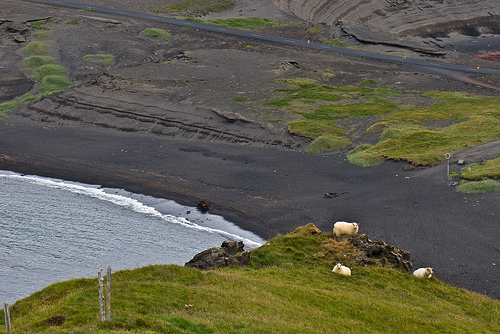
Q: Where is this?
A: This is at the beach.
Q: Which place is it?
A: It is a beach.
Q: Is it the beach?
A: Yes, it is the beach.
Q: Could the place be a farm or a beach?
A: It is a beach.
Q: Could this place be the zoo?
A: No, it is the beach.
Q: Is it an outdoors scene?
A: Yes, it is outdoors.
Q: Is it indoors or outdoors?
A: It is outdoors.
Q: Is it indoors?
A: No, it is outdoors.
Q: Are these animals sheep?
A: Yes, all the animals are sheep.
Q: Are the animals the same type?
A: Yes, all the animals are sheep.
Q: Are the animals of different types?
A: No, all the animals are sheep.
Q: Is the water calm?
A: Yes, the water is calm.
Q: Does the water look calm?
A: Yes, the water is calm.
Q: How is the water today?
A: The water is calm.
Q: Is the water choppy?
A: No, the water is calm.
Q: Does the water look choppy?
A: No, the water is calm.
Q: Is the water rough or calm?
A: The water is calm.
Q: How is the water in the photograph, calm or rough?
A: The water is calm.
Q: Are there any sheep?
A: Yes, there is a sheep.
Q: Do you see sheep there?
A: Yes, there is a sheep.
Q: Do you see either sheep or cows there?
A: Yes, there is a sheep.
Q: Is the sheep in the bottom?
A: Yes, the sheep is in the bottom of the image.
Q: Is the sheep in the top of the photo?
A: No, the sheep is in the bottom of the image.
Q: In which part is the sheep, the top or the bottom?
A: The sheep is in the bottom of the image.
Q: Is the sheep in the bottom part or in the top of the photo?
A: The sheep is in the bottom of the image.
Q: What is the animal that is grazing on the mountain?
A: The animal is a sheep.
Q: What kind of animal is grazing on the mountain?
A: The animal is a sheep.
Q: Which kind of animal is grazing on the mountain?
A: The animal is a sheep.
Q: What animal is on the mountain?
A: The animal is a sheep.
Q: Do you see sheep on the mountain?
A: Yes, there is a sheep on the mountain.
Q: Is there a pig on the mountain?
A: No, there is a sheep on the mountain.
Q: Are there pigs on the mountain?
A: No, there is a sheep on the mountain.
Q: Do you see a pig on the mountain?
A: No, there is a sheep on the mountain.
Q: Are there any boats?
A: No, there are no boats.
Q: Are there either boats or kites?
A: No, there are no boats or kites.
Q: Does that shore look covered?
A: Yes, the shore is covered.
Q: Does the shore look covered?
A: Yes, the shore is covered.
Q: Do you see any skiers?
A: No, there are no skiers.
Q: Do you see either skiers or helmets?
A: No, there are no skiers or helmets.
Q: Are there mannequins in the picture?
A: No, there are no mannequins.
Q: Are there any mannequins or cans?
A: No, there are no mannequins or cans.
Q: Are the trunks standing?
A: Yes, the trunks are standing.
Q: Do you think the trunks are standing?
A: Yes, the trunks are standing.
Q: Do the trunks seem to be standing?
A: Yes, the trunks are standing.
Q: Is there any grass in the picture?
A: Yes, there is grass.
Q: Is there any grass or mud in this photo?
A: Yes, there is grass.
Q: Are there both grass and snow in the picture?
A: No, there is grass but no snow.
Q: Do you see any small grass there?
A: Yes, there is small grass.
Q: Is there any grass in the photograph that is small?
A: Yes, there is grass that is small.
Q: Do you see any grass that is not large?
A: Yes, there is small grass.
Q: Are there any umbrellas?
A: No, there are no umbrellas.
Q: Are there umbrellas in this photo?
A: No, there are no umbrellas.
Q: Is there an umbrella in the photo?
A: No, there are no umbrellas.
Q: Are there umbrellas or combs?
A: No, there are no umbrellas or combs.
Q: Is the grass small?
A: Yes, the grass is small.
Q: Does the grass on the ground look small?
A: Yes, the grass is small.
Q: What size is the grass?
A: The grass is small.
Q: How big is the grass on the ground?
A: The grass is small.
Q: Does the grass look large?
A: No, the grass is small.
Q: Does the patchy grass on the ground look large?
A: No, the grass is small.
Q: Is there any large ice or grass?
A: No, there is grass but it is small.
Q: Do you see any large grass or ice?
A: No, there is grass but it is small.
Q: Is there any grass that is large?
A: No, there is grass but it is small.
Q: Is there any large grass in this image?
A: No, there is grass but it is small.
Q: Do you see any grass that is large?
A: No, there is grass but it is small.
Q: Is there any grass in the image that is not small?
A: No, there is grass but it is small.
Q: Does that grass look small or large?
A: The grass is small.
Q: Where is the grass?
A: The grass is on the ground.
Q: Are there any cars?
A: No, there are no cars.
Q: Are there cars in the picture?
A: No, there are no cars.